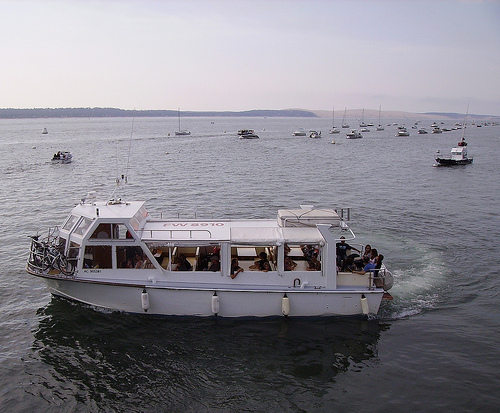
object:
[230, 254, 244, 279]
person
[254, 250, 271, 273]
person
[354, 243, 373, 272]
person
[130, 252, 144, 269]
person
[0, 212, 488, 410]
forefront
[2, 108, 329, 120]
land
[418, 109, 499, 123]
land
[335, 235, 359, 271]
people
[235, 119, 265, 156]
boat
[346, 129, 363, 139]
boat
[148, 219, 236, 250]
railing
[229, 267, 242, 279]
arm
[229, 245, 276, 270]
window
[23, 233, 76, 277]
bikes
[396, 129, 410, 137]
boats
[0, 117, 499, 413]
water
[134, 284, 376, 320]
bouys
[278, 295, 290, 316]
buoy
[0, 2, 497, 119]
sky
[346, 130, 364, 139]
boat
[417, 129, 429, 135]
boat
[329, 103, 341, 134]
boat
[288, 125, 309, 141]
boat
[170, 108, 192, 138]
boat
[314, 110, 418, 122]
hill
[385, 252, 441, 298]
bubbles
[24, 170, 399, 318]
boat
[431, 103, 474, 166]
boat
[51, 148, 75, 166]
bouy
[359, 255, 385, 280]
person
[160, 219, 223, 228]
number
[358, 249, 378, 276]
person